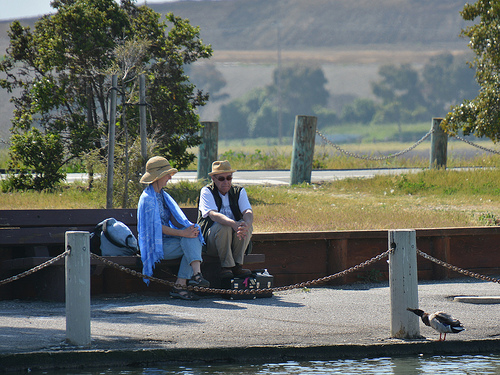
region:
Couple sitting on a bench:
[136, 151, 254, 298]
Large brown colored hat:
[139, 150, 176, 185]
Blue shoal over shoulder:
[138, 191, 203, 285]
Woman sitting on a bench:
[135, 156, 208, 298]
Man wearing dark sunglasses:
[215, 159, 237, 193]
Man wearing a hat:
[211, 160, 237, 190]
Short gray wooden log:
[64, 229, 94, 346]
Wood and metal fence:
[3, 233, 499, 346]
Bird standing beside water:
[406, 301, 465, 341]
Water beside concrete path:
[0, 348, 499, 374]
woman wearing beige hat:
[132, 130, 204, 291]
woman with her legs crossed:
[138, 155, 206, 293]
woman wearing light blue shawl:
[129, 141, 206, 293]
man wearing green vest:
[200, 160, 273, 287]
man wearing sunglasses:
[201, 148, 268, 295]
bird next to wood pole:
[397, 295, 493, 362]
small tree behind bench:
[30, 20, 181, 175]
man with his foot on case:
[196, 155, 291, 292]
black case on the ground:
[220, 265, 270, 296]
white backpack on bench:
[86, 207, 137, 260]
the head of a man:
[208, 165, 240, 200]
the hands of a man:
[223, 212, 249, 241]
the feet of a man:
[212, 262, 267, 287]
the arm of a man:
[194, 189, 244, 250]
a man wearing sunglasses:
[207, 150, 247, 200]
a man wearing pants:
[205, 187, 296, 271]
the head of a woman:
[141, 142, 189, 203]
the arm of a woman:
[134, 201, 203, 253]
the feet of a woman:
[149, 249, 234, 315]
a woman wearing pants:
[142, 217, 227, 290]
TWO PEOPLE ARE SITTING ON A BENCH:
[133, 151, 269, 298]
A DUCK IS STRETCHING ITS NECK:
[401, 298, 464, 343]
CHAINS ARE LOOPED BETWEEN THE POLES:
[87, 247, 387, 302]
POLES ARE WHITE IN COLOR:
[61, 227, 106, 342]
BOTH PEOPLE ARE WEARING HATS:
[133, 149, 267, 194]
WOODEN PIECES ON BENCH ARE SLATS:
[1, 211, 105, 239]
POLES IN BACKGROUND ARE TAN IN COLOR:
[278, 112, 469, 189]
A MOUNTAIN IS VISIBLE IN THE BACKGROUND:
[1, 8, 470, 65]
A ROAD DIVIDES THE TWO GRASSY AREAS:
[9, 166, 494, 190]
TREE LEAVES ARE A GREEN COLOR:
[16, 12, 211, 164]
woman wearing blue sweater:
[133, 159, 210, 309]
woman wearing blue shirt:
[133, 157, 207, 297]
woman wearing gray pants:
[125, 158, 208, 299]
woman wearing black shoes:
[136, 158, 208, 304]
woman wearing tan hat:
[133, 159, 207, 303]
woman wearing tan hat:
[198, 162, 252, 286]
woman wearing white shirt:
[197, 166, 254, 282]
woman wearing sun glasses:
[198, 162, 253, 276]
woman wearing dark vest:
[196, 159, 256, 276]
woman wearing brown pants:
[199, 160, 252, 282]